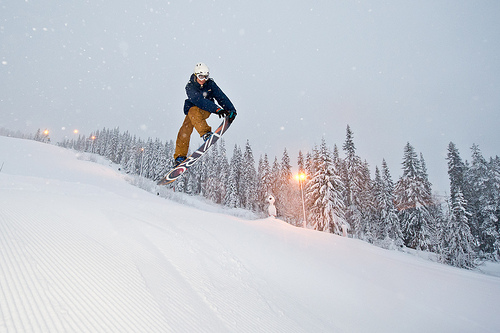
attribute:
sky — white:
[37, 12, 466, 129]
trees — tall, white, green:
[244, 147, 478, 244]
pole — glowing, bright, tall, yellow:
[294, 163, 319, 215]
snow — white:
[9, 155, 394, 327]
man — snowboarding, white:
[154, 52, 247, 206]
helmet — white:
[192, 56, 212, 77]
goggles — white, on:
[198, 72, 211, 82]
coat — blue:
[183, 83, 222, 105]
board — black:
[162, 117, 248, 199]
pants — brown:
[172, 112, 213, 140]